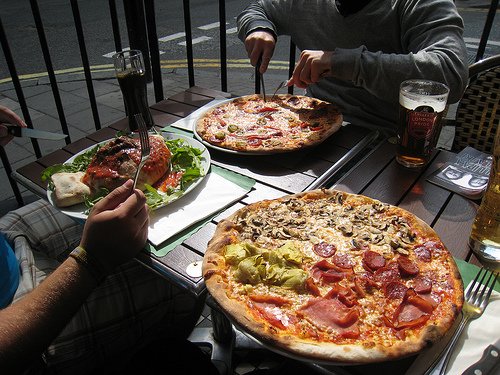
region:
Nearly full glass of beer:
[388, 67, 454, 183]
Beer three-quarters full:
[96, 45, 159, 133]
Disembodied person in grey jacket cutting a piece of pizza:
[219, 2, 465, 114]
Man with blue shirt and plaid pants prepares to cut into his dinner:
[1, 97, 196, 372]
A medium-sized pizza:
[196, 74, 343, 166]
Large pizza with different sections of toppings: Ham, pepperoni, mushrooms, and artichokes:
[202, 175, 459, 373]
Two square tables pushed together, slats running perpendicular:
[111, 121, 498, 313]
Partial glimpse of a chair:
[453, 50, 499, 147]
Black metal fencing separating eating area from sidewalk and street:
[4, 4, 164, 111]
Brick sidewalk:
[6, 74, 121, 129]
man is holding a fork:
[139, 123, 155, 223]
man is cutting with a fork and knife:
[216, 33, 323, 109]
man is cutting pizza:
[238, 31, 345, 140]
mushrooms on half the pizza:
[244, 180, 434, 253]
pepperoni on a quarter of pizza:
[323, 245, 472, 355]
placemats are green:
[198, 158, 268, 193]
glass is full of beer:
[395, 75, 455, 168]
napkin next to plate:
[161, 166, 243, 229]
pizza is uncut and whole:
[229, 167, 462, 347]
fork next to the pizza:
[443, 262, 496, 360]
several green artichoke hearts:
[229, 246, 299, 286]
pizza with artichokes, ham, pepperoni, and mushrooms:
[198, 186, 467, 364]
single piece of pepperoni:
[361, 249, 388, 271]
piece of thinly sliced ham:
[302, 297, 359, 335]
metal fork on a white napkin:
[407, 263, 499, 374]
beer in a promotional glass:
[388, 76, 453, 173]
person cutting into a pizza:
[190, 0, 473, 173]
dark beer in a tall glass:
[108, 43, 160, 134]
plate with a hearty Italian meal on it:
[36, 125, 213, 220]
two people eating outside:
[1, 1, 498, 373]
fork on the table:
[457, 253, 491, 373]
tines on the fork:
[466, 262, 495, 308]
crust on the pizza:
[211, 332, 383, 354]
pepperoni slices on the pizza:
[331, 240, 438, 289]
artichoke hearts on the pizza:
[221, 245, 308, 297]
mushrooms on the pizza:
[241, 204, 392, 239]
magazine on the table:
[423, 140, 493, 220]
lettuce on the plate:
[186, 120, 215, 190]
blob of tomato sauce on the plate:
[154, 163, 183, 207]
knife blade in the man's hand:
[6, 118, 72, 151]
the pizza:
[195, 106, 393, 372]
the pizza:
[180, 157, 300, 345]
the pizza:
[256, 217, 323, 370]